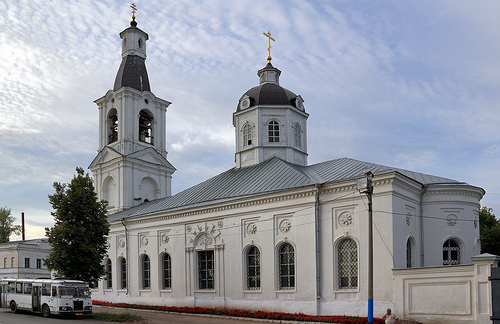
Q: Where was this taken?
A: Outside of a church.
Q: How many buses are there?
A: 1.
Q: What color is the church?
A: White.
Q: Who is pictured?
A: No one.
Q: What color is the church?
A: White.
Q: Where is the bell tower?
A: On top of building.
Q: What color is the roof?
A: Gray.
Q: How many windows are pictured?
A: 16.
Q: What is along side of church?
A: Red flowers.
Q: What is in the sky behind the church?
A: Blue sky.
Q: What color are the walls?
A: White.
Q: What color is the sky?
A: Blue and white.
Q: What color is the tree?
A: Green.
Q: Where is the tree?
A: In Front of the church.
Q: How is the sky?
A: Cloudy.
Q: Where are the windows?
A: In the wall of the building.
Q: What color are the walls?
A: White.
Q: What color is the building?
A: White.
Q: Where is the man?
A: At the front of the building.